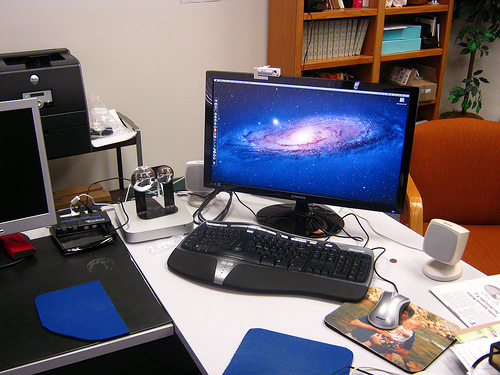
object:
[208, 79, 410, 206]
computer monitor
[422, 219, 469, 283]
speaker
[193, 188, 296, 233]
cables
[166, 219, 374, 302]
computer keyboard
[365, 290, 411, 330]
mouse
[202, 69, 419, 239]
computer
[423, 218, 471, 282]
computer speaker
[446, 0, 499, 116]
houseplant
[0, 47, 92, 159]
black printer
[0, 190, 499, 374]
tabletop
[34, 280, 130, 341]
pad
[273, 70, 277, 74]
webcam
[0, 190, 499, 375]
ground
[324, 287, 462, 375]
mouse pad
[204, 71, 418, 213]
screen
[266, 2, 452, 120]
bookcase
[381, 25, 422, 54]
two boxes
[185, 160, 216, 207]
speaker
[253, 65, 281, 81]
clip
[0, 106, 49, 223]
monitor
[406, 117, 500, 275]
chair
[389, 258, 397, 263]
penny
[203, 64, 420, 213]
desktop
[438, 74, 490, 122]
corner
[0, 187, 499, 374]
desk